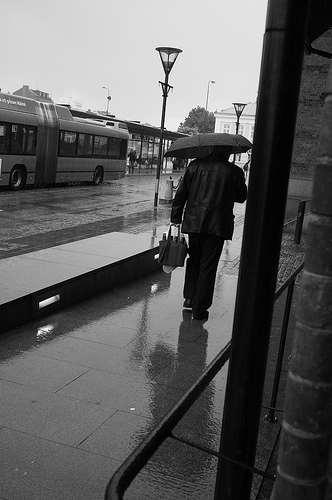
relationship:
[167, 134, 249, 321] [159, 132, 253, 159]
man carrying umbrella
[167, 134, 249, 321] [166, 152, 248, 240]
man wearing jacket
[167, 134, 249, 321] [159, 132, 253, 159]
man holding umbrella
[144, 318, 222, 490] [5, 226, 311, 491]
shadow on street